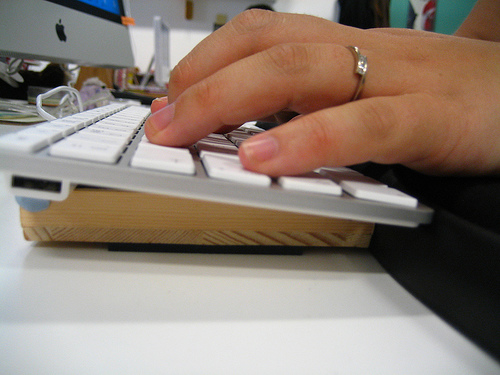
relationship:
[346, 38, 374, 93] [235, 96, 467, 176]
ring on finger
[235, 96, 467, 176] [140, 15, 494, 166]
finger of hand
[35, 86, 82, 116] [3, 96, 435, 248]
wire behind keyboard